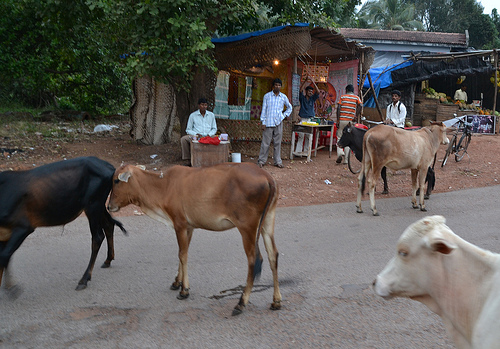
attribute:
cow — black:
[1, 154, 129, 302]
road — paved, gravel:
[0, 184, 499, 348]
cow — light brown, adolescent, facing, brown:
[106, 160, 282, 316]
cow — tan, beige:
[355, 121, 451, 218]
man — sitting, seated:
[178, 97, 218, 164]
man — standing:
[256, 77, 293, 169]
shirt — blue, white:
[260, 92, 294, 128]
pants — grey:
[257, 121, 284, 167]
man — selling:
[454, 83, 469, 104]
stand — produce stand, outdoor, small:
[413, 85, 500, 134]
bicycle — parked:
[440, 113, 473, 168]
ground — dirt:
[1, 118, 498, 216]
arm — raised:
[298, 74, 309, 103]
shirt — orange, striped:
[337, 93, 362, 123]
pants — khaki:
[336, 119, 355, 164]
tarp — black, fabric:
[389, 55, 494, 90]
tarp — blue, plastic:
[356, 61, 415, 110]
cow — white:
[371, 215, 500, 348]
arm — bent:
[284, 97, 293, 117]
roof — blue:
[213, 22, 376, 64]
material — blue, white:
[213, 68, 254, 122]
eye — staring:
[398, 248, 409, 258]